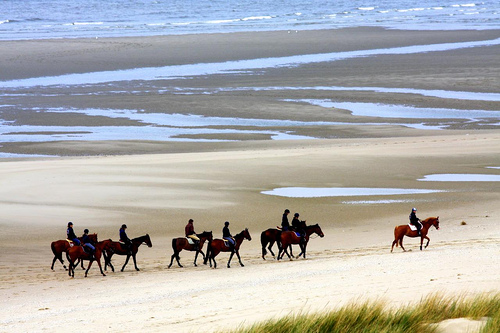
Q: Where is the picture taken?
A: A beach.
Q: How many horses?
A: Eight.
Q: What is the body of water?
A: An ocean.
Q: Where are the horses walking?
A: On shore.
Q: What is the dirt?
A: Sand.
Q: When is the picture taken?
A: Daytime.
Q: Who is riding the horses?
A: People.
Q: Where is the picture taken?
A: On a beach.